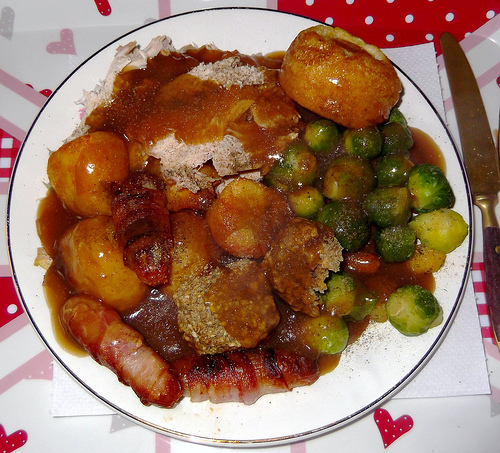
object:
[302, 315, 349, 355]
veggie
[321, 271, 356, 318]
green veggie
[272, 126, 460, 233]
brussels sprouts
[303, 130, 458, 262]
veggie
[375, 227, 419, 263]
veggie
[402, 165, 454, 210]
veggie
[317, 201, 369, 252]
veggie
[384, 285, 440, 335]
sprout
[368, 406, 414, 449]
heart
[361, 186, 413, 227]
vegetable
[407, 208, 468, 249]
brussel sprout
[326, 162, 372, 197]
brussel sprout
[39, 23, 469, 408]
food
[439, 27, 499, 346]
knife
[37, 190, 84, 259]
gravy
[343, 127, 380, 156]
brussel sprout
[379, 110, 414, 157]
brussel sprout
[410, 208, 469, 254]
brussel sprout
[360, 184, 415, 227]
brussel sprout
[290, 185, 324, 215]
brussel sprout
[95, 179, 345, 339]
food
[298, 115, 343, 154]
veggie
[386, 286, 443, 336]
brussel sprout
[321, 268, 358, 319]
brussel sprout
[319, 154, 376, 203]
veggie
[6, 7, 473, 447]
plate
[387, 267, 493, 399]
napkin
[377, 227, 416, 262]
brussel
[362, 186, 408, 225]
brussel sprout